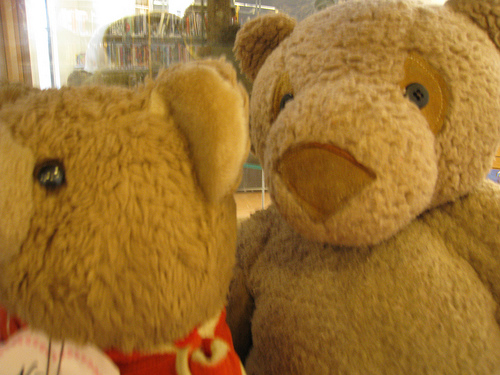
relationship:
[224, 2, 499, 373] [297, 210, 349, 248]
teddy bear has mouth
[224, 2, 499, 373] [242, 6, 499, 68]
teddy bear has ears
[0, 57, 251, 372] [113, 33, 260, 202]
teddy bear has ear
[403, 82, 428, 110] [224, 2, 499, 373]
button eye of teddy bear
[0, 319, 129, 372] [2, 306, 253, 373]
patch on outfit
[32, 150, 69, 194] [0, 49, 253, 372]
eye of bear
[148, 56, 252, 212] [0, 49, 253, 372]
ear of bear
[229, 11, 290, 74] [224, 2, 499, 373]
ear of teddy bear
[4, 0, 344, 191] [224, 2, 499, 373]
window behind teddy bear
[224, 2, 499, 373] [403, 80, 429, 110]
teddy bear with eye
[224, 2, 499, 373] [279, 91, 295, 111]
teddy bear with eye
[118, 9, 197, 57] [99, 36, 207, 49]
books on shelves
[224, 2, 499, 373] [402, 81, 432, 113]
teddy bear with button eye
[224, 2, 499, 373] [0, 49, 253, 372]
teddy bear beside bear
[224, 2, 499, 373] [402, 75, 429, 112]
teddy bear with eye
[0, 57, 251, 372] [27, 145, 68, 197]
teddy bear with eye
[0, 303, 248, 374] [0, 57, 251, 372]
shirt on teddy bear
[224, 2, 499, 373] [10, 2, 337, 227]
teddy bear in front of window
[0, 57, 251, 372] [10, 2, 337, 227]
teddy bear in front of window